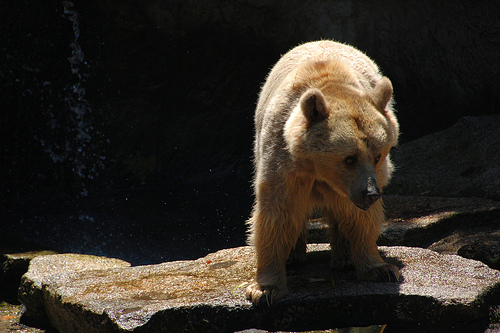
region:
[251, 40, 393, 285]
brown and white bear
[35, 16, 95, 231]
water dripping to pool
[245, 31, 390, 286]
bear standing on rock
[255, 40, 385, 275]
bear looking for food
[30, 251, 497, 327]
flat grey and brown rock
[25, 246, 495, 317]
grey rock on ground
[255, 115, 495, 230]
flat rock on ground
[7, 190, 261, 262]
swimming pool by rocks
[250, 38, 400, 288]
bear waiting for water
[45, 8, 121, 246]
Water falling onto rocks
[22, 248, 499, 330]
Large flat stone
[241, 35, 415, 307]
Polar bear standing on all 4 legs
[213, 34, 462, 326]
White bear on the rocks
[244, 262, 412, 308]
Long claws on bear's front paws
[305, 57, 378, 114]
Cream colored ruff on a polar bear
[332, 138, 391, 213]
Long snout of a white bear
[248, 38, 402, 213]
Sun shining on the white back fur of a bear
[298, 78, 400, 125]
Two fluffy bear ears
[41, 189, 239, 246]
Water droplets splashing against rocks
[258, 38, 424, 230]
bear outside somewhere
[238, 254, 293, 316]
paw of the bear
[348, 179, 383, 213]
nose of the bear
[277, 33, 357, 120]
brown fur of the bear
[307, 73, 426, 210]
bear looking to the left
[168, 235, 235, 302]
light shining on rock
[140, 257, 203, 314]
rock below the bear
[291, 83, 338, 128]
ear on the bear's head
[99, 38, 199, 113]
dark background of the photo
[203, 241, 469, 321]
shadow under the bear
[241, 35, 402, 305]
a polar bear is in the sun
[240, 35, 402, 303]
the polar bear is standing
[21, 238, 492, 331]
the bear is on a flat rock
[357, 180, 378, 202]
the bear has a black nose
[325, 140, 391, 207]
the bear has a sad look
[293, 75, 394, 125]
the bear has fluffy ears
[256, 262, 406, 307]
claws are on the bear's paws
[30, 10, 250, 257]
a trickle waterfall is behind the bear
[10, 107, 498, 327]
flat rocks are around the enclosure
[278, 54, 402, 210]
the bear's fur is darker on the top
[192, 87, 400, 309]
bear on a stone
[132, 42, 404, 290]
bear on a stone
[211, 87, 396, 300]
bear on a stone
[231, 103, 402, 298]
bear on a stone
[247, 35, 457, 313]
bear on a stone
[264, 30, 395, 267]
bear on a stone